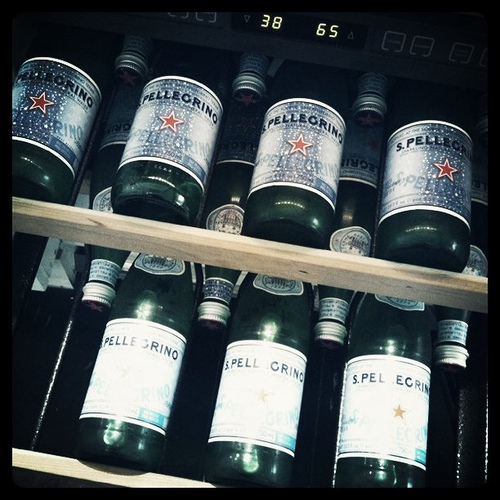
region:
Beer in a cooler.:
[55, 44, 406, 495]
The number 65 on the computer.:
[317, 15, 339, 40]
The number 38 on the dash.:
[251, 13, 296, 38]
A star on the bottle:
[394, 400, 406, 420]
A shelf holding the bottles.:
[34, 202, 489, 337]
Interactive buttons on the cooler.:
[380, 24, 492, 69]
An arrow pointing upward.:
[347, 28, 356, 40]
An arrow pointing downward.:
[241, 10, 251, 24]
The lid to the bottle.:
[319, 319, 347, 349]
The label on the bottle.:
[122, 73, 223, 204]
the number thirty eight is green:
[260, 11, 285, 32]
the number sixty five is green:
[317, 19, 339, 39]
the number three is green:
[261, 12, 271, 27]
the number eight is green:
[273, 15, 282, 30]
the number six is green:
[316, 21, 326, 39]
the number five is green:
[329, 22, 339, 37]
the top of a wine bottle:
[232, 57, 264, 103]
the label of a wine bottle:
[225, 341, 298, 448]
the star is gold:
[388, 402, 407, 418]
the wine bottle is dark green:
[242, 294, 306, 343]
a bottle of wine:
[13, 42, 123, 205]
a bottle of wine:
[97, 46, 142, 226]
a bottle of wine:
[108, 38, 235, 225]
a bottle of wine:
[217, 43, 278, 242]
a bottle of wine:
[328, 55, 379, 252]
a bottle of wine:
[370, 60, 487, 282]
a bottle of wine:
[321, 279, 427, 494]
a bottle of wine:
[212, 265, 297, 489]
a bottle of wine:
[73, 246, 208, 491]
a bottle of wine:
[10, 240, 103, 453]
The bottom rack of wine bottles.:
[22, 264, 482, 494]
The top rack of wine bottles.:
[10, 18, 487, 266]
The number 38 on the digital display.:
[259, 13, 296, 34]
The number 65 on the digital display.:
[315, 23, 336, 44]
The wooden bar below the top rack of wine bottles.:
[15, 193, 493, 310]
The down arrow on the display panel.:
[239, 13, 254, 22]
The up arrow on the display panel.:
[343, 24, 358, 46]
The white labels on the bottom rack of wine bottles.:
[85, 313, 428, 466]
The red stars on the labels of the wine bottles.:
[20, 92, 461, 166]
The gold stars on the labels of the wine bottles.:
[108, 357, 411, 432]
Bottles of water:
[23, 20, 493, 477]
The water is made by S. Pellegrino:
[23, 92, 468, 467]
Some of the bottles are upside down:
[28, 76, 478, 378]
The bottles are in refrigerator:
[20, 15, 470, 477]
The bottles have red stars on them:
[29, 101, 470, 210]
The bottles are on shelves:
[27, 427, 294, 499]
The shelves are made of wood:
[30, 430, 247, 490]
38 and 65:
[241, 6, 392, 51]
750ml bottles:
[163, 142, 190, 165]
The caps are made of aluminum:
[63, 270, 476, 371]